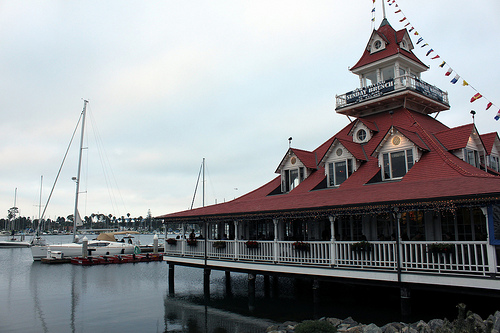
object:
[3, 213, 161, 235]
trees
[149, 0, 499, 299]
building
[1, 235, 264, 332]
water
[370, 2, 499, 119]
flags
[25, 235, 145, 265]
boat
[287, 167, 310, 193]
window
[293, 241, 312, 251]
flower box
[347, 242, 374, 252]
flower box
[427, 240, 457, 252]
flower box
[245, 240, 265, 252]
flower box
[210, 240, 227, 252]
flower box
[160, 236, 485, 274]
rail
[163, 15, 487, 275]
building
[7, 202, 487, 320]
harbor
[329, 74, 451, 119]
platform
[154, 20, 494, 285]
red building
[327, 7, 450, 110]
top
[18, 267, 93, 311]
water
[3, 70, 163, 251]
harbor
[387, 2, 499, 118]
pendants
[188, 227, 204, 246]
person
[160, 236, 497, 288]
porch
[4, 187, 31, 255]
sailboat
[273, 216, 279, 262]
wooden bar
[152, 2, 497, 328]
buidling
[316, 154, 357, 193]
windows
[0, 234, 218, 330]
water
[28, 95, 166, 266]
boat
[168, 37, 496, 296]
building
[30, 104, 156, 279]
boat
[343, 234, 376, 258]
flowers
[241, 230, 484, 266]
gate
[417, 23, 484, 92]
plastic cup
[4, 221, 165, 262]
boats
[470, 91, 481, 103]
flag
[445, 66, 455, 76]
flag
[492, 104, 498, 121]
flag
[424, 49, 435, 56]
flag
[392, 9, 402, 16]
flag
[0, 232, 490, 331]
water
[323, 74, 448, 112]
railing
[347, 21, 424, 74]
roof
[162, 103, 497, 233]
roof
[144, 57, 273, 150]
sky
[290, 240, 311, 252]
flowers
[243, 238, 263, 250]
flowers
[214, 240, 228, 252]
flowers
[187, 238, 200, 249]
flowers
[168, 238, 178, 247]
flowers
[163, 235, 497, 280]
railing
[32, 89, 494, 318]
building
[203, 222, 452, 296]
railing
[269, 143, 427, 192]
windows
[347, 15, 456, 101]
building top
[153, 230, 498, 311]
porch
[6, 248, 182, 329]
water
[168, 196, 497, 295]
building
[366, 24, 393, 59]
peak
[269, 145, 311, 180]
peak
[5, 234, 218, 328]
harbor